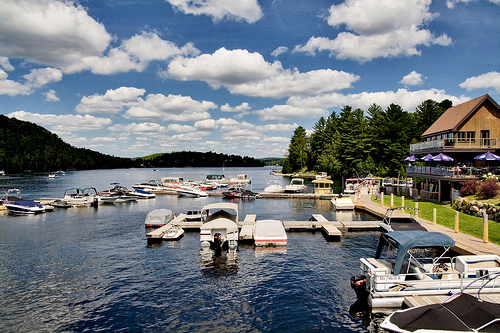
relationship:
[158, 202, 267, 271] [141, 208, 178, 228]
dock has ship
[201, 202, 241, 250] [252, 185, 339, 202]
boat parked at dock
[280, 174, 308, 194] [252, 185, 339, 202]
boat parked at dock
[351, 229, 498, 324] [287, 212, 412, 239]
boat parked at dock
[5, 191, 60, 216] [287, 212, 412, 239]
boat parked at dock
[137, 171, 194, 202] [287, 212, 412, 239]
boat parked at dock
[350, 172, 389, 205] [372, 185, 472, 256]
people walking on boardwalk